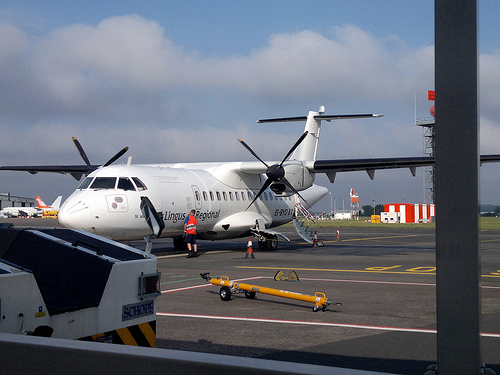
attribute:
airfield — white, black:
[306, 190, 471, 258]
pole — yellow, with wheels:
[220, 259, 342, 314]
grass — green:
[308, 216, 498, 231]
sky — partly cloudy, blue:
[0, 0, 499, 204]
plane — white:
[0, 111, 500, 252]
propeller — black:
[234, 129, 312, 210]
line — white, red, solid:
[218, 312, 304, 331]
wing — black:
[302, 157, 498, 180]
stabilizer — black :
[253, 110, 387, 126]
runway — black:
[275, 227, 439, 334]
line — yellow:
[246, 259, 373, 278]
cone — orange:
[243, 234, 255, 260]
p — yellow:
[364, 260, 400, 274]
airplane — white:
[2, 104, 483, 252]